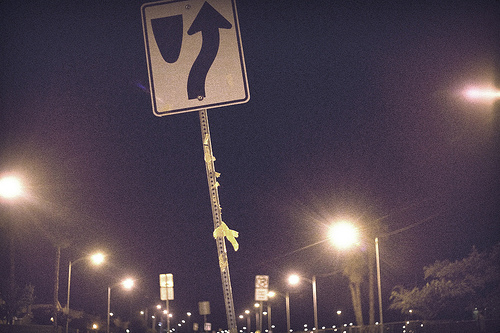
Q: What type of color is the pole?
A: Gray.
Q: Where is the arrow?
A: On the sign.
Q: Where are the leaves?
A: On the trees.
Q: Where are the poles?
A: On the ground.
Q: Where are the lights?
A: In the air.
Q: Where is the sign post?
A: In the ground.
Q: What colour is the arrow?
A: Black.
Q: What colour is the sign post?
A: Gray.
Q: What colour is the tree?
A: Green.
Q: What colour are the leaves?
A: Green.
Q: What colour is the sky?
A: Black.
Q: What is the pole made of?
A: Metal.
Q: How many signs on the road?
A: One.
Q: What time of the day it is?
A: Night time.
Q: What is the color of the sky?
A: Black.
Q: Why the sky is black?
A: It's evening.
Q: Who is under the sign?
A: No one.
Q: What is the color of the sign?
A: White and black.